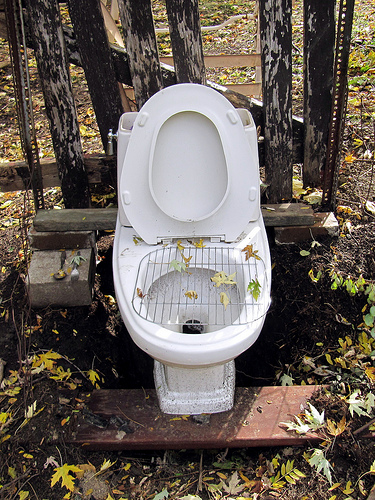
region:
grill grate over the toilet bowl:
[119, 240, 272, 341]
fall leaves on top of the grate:
[114, 236, 284, 324]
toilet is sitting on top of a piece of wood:
[24, 362, 342, 467]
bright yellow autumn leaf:
[43, 445, 92, 496]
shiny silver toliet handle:
[99, 127, 125, 160]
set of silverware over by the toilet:
[48, 242, 83, 292]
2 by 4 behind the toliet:
[24, 197, 341, 250]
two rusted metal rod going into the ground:
[1, 6, 367, 210]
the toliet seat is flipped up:
[107, 79, 278, 261]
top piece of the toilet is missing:
[104, 94, 264, 149]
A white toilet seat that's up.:
[119, 82, 259, 244]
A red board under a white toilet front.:
[77, 384, 332, 447]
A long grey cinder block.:
[25, 250, 94, 305]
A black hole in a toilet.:
[184, 318, 204, 333]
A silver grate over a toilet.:
[132, 243, 271, 325]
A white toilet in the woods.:
[114, 83, 272, 414]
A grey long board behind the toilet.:
[31, 203, 313, 230]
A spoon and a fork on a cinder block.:
[52, 248, 80, 280]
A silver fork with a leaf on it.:
[69, 249, 81, 282]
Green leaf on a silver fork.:
[69, 254, 86, 265]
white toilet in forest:
[97, 81, 280, 419]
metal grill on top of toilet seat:
[127, 243, 271, 327]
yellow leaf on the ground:
[41, 445, 91, 494]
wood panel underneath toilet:
[66, 379, 344, 451]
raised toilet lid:
[107, 77, 263, 247]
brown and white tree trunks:
[27, 3, 336, 208]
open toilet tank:
[112, 105, 264, 211]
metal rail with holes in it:
[2, 2, 48, 214]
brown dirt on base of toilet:
[154, 366, 237, 417]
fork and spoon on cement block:
[46, 248, 89, 283]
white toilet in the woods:
[109, 91, 280, 418]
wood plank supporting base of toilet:
[79, 386, 324, 444]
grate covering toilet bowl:
[136, 241, 271, 334]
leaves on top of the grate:
[143, 235, 276, 310]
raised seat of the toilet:
[119, 86, 256, 234]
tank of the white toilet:
[117, 113, 261, 219]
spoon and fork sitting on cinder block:
[49, 254, 83, 281]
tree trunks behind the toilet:
[6, 7, 351, 219]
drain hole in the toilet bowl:
[180, 316, 199, 333]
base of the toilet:
[150, 363, 232, 411]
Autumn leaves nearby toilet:
[231, 464, 314, 492]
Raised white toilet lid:
[121, 82, 253, 273]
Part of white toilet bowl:
[163, 335, 226, 353]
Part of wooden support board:
[61, 402, 140, 436]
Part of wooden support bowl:
[247, 399, 292, 432]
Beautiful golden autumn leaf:
[44, 459, 84, 493]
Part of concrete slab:
[38, 264, 86, 291]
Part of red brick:
[34, 236, 83, 245]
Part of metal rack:
[156, 261, 227, 301]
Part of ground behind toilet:
[216, 27, 256, 49]